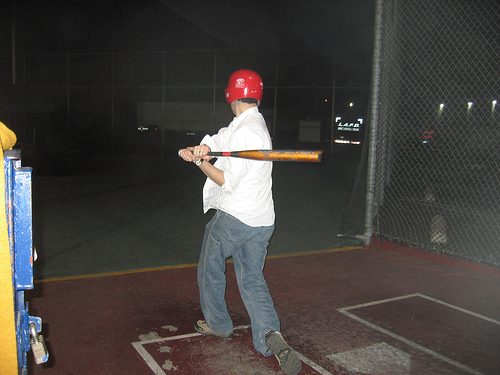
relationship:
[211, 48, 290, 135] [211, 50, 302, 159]
helmet on head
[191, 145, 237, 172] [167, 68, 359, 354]
watch on man